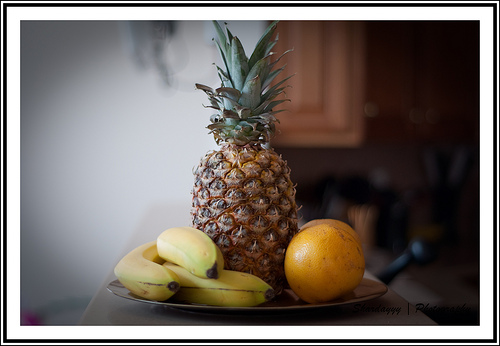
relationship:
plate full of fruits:
[100, 276, 389, 314] [189, 20, 302, 306]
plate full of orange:
[100, 276, 389, 314] [283, 218, 366, 300]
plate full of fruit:
[100, 276, 389, 314] [150, 223, 232, 282]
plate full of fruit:
[100, 276, 389, 314] [154, 250, 279, 309]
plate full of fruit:
[100, 276, 389, 314] [110, 237, 182, 304]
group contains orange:
[284, 216, 366, 306] [280, 224, 366, 305]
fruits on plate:
[189, 20, 302, 306] [100, 276, 389, 314]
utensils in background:
[423, 138, 495, 253] [20, 20, 480, 324]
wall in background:
[18, 22, 270, 327] [20, 20, 480, 324]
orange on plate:
[283, 220, 366, 301] [108, 271, 388, 308]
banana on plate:
[108, 208, 282, 310] [101, 262, 421, 316]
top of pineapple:
[194, 20, 293, 137] [194, 21, 298, 294]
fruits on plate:
[189, 20, 302, 306] [98, 265, 401, 312]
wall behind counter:
[68, 122, 136, 187] [87, 200, 439, 330]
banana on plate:
[116, 232, 176, 304] [106, 256, 389, 313]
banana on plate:
[157, 221, 222, 271] [106, 256, 389, 313]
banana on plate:
[158, 260, 274, 307] [106, 256, 389, 313]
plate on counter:
[100, 276, 389, 314] [99, 280, 476, 340]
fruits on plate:
[118, 20, 374, 305] [100, 276, 393, 314]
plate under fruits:
[100, 276, 389, 314] [189, 20, 302, 306]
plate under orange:
[100, 276, 389, 314] [280, 224, 366, 305]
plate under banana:
[100, 276, 389, 314] [153, 221, 221, 281]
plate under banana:
[100, 276, 389, 314] [111, 240, 181, 306]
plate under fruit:
[100, 276, 389, 314] [163, 260, 273, 310]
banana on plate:
[153, 221, 221, 281] [100, 276, 389, 314]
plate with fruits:
[100, 276, 389, 314] [189, 20, 302, 306]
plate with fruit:
[100, 276, 389, 314] [280, 215, 359, 310]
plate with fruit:
[100, 276, 389, 314] [158, 224, 220, 281]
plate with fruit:
[100, 276, 389, 314] [120, 240, 173, 300]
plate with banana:
[100, 276, 389, 314] [158, 260, 274, 307]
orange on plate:
[280, 216, 376, 306] [105, 283, 390, 312]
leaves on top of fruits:
[210, 20, 287, 149] [189, 20, 302, 306]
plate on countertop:
[100, 276, 393, 314] [78, 198, 438, 327]